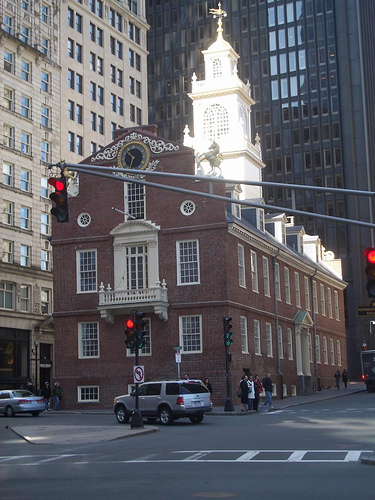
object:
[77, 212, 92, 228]
window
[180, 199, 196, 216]
window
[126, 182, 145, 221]
window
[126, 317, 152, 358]
window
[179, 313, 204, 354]
window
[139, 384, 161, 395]
window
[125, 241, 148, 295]
window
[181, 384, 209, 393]
back window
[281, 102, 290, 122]
window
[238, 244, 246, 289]
window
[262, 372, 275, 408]
group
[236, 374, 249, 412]
person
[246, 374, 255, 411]
person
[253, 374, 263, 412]
person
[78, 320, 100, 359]
window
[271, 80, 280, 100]
window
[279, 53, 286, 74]
window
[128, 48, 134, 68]
window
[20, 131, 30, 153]
window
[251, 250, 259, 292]
window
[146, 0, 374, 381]
building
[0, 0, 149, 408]
building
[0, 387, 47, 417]
car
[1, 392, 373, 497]
street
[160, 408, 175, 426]
tire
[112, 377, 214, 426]
suv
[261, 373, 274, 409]
person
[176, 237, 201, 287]
window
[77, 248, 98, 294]
window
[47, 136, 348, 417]
building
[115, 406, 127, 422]
wheel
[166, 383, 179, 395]
window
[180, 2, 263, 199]
building